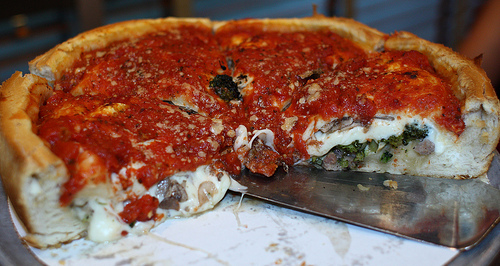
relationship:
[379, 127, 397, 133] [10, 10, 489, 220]
cheese amongst a pizza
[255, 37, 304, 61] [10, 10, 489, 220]
sauce on top of pizza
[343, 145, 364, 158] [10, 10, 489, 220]
spinach on pizza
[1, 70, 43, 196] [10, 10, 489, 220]
crust of a pizza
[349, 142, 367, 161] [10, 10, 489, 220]
spinach amongst a pizza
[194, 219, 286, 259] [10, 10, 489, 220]
cardboard under pizza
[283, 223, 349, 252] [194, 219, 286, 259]
grease intertwined with board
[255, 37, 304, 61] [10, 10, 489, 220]
sauce on pizza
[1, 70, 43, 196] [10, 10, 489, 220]
crust of pizza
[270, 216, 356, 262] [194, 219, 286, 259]
grease stains on paper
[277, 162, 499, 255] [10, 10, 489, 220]
spatula under a pizza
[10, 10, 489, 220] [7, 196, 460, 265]
pizza on cardboard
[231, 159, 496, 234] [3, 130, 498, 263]
pizza cutter on board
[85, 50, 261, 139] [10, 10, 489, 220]
seasoning on pizza